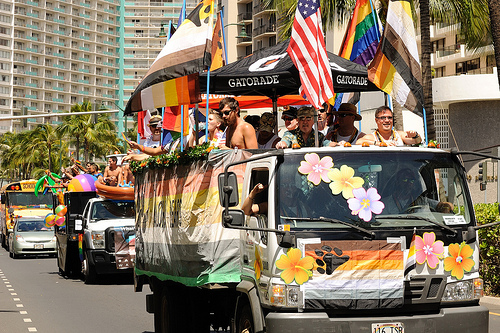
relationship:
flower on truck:
[276, 241, 314, 290] [132, 138, 472, 331]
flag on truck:
[287, 1, 336, 118] [132, 138, 472, 331]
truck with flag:
[132, 138, 472, 331] [287, 1, 336, 118]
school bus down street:
[4, 178, 58, 236] [1, 136, 500, 332]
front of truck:
[261, 149, 481, 330] [132, 138, 472, 331]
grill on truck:
[269, 282, 487, 329] [132, 138, 472, 331]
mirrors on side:
[216, 175, 251, 235] [139, 158, 289, 294]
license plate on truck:
[369, 321, 396, 331] [132, 138, 472, 331]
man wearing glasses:
[214, 94, 255, 159] [220, 108, 235, 118]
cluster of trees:
[2, 104, 121, 160] [4, 117, 117, 174]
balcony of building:
[440, 66, 500, 112] [436, 13, 498, 156]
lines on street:
[0, 263, 44, 328] [1, 136, 500, 332]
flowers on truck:
[300, 156, 388, 227] [132, 138, 472, 331]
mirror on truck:
[360, 161, 385, 176] [132, 138, 472, 331]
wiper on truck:
[285, 214, 382, 242] [132, 138, 472, 331]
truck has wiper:
[132, 138, 472, 331] [285, 214, 382, 242]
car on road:
[11, 216, 59, 256] [2, 208, 176, 330]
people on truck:
[197, 97, 398, 148] [132, 138, 472, 331]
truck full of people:
[132, 138, 472, 331] [197, 97, 398, 148]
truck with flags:
[132, 138, 472, 331] [150, 0, 443, 120]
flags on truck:
[150, 0, 443, 120] [132, 138, 472, 331]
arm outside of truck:
[239, 178, 267, 223] [132, 138, 472, 331]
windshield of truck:
[281, 154, 465, 233] [132, 138, 472, 331]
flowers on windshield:
[300, 156, 388, 227] [281, 154, 465, 233]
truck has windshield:
[132, 138, 472, 331] [281, 154, 465, 233]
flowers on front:
[300, 156, 388, 227] [261, 149, 481, 330]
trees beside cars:
[4, 117, 117, 174] [5, 164, 127, 260]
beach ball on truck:
[66, 170, 97, 196] [64, 179, 138, 276]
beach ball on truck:
[68, 172, 99, 192] [64, 179, 138, 276]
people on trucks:
[197, 97, 398, 148] [132, 138, 472, 331]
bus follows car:
[2, 177, 48, 210] [11, 216, 59, 256]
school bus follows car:
[4, 178, 58, 236] [11, 216, 59, 256]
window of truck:
[300, 156, 388, 227] [132, 138, 472, 331]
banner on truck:
[300, 241, 416, 292] [132, 138, 472, 331]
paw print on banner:
[311, 241, 352, 278] [300, 241, 416, 292]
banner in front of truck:
[300, 241, 416, 292] [132, 138, 472, 331]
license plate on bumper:
[369, 321, 396, 331] [266, 309, 487, 331]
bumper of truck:
[266, 309, 487, 331] [132, 138, 472, 331]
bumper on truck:
[266, 309, 487, 331] [132, 138, 472, 331]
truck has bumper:
[132, 138, 472, 331] [266, 309, 487, 331]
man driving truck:
[387, 165, 465, 227] [132, 138, 472, 331]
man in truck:
[387, 165, 465, 227] [132, 138, 472, 331]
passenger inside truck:
[255, 168, 319, 219] [132, 138, 472, 331]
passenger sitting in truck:
[255, 168, 319, 219] [132, 138, 472, 331]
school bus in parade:
[4, 178, 58, 236] [16, 19, 465, 301]